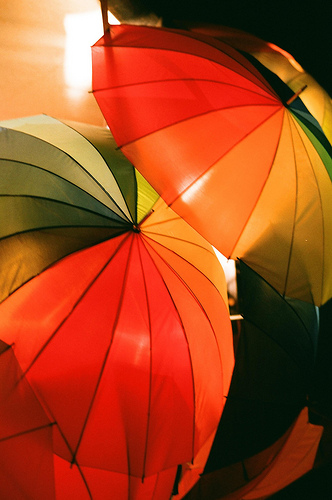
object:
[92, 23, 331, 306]
umbrella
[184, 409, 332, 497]
floor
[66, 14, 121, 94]
light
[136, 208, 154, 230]
spine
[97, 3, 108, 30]
pole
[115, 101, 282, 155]
wires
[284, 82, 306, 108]
connector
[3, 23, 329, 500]
group